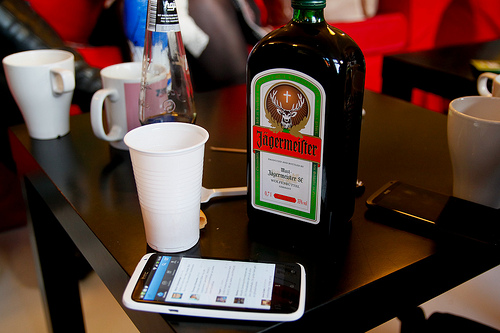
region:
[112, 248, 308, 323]
a white cellphone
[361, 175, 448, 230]
part of a black cellphone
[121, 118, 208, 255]
a tall white cup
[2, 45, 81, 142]
a tall coffee mug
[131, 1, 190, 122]
part of a glass bottle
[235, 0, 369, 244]
part of a glass alcohol bottle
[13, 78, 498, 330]
a small brown table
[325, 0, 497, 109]
part of a red couch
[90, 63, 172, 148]
a pink and white coffee mug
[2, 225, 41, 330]
part of a white floor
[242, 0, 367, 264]
bottle of jagermeister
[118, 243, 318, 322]
smart phone with white case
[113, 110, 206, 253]
white plastic cup with ridges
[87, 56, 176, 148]
white coffee mug with pink design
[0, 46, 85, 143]
white coffee mug that is more slender at bottom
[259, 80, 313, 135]
logo with deer with antlers and cross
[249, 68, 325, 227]
label of jagermeister bottle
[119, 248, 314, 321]
social media app on smart phone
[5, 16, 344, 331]
table with bottles and cups and phone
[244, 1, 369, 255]
dark liquor bottle with red label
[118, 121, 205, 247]
White cup on the table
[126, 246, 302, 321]
mobile device on the table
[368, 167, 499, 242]
cellphone on the table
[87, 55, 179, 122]
coffee mug on the table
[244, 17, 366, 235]
Liquor bottle on the table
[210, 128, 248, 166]
stick on the table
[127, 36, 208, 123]
glass bottle on the table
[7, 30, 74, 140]
white coffee mug on the table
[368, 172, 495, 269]
black cellphone on the table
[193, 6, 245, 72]
person sitting on the sofa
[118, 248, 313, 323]
big white cell phone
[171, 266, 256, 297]
white color on the phone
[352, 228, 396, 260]
gold color on top of table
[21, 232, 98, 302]
black legs on table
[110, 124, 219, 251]
large white plastic cup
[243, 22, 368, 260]
tall black whiskey bottle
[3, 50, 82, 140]
white cup with handle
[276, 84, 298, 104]
small cross on bottle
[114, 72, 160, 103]
pink color on cup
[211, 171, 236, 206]
white spoon on table top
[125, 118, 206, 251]
a white plastic cup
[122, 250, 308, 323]
a white smart phone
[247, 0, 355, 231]
a bottle of jagermeister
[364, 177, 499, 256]
a smartphone that is turned off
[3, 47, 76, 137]
a white ceramic mug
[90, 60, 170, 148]
a white ceramic mug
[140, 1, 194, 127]
a thin glass bottle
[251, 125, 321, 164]
red label for jagermeister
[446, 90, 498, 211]
a white coffee mug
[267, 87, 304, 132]
logo with a deer head